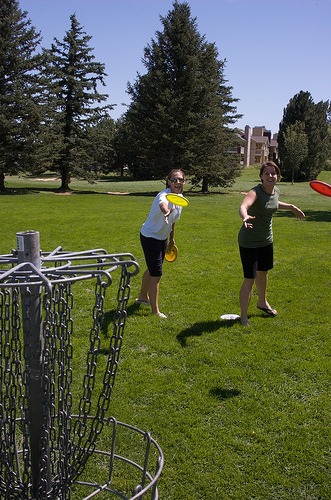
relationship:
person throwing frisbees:
[237, 161, 306, 332] [169, 177, 329, 209]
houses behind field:
[228, 127, 279, 169] [1, 175, 330, 495]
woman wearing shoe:
[238, 163, 308, 321] [254, 301, 276, 319]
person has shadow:
[238, 163, 308, 321] [177, 317, 242, 346]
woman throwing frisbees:
[139, 171, 189, 318] [164, 191, 189, 208]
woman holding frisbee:
[139, 171, 189, 318] [164, 240, 176, 263]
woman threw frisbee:
[238, 163, 308, 321] [307, 179, 330, 201]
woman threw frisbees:
[139, 171, 189, 318] [164, 191, 189, 208]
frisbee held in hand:
[164, 240, 176, 263] [167, 236, 176, 247]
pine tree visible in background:
[42, 15, 110, 181] [1, 1, 328, 198]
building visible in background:
[225, 126, 280, 168] [1, 1, 328, 198]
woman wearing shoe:
[238, 163, 308, 321] [254, 301, 280, 317]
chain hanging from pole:
[77, 286, 107, 437] [15, 230, 47, 500]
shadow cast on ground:
[177, 317, 242, 346] [152, 299, 290, 370]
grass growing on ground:
[4, 182, 330, 495] [152, 299, 290, 370]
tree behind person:
[116, 5, 211, 179] [237, 161, 306, 332]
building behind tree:
[225, 126, 280, 168] [116, 5, 211, 179]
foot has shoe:
[255, 300, 278, 317] [254, 301, 276, 319]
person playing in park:
[237, 161, 306, 332] [1, 175, 330, 495]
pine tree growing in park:
[42, 15, 110, 181] [1, 175, 330, 495]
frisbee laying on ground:
[218, 310, 241, 325] [152, 299, 290, 370]